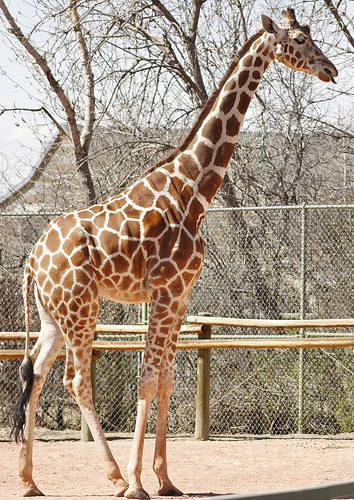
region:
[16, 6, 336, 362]
standing giraffe in enclosure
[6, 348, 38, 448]
black hair on tail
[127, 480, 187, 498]
hooves on giraffe feet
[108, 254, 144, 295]
brown spots on belly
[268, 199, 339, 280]
chain link fence and pole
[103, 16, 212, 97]
tree with no leaves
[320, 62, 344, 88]
tongue sticking out of mouth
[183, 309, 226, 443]
wood on fence post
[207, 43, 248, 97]
mane on giraffe neck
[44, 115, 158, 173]
roof of building behind trees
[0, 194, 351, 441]
fence around area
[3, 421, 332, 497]
giraffe standing on dusty ground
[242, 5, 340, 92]
giraffe sticking tongue out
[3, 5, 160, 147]
trees have no leaves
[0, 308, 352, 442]
wooden post fence in front of wired fence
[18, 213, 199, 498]
giraffe rear right leg stepping forward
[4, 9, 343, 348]
giraffe with brown pattern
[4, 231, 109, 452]
giraffe tail is brown, tan, and black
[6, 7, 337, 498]
giraffe is taller than both fences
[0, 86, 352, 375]
building in the background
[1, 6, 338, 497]
A Large Giraffe standing in the open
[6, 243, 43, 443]
The Giraffes Tail hanging low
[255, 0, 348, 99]
The Giraffe's Head held high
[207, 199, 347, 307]
Metal Chain Link Fencing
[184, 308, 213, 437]
A Wood Fence Post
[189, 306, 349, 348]
The Wooden Fence Railing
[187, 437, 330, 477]
Bare Patch of Ground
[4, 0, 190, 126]
Trees with no leaves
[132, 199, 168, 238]
The Giraffe's Spots on his back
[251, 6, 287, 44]
The Giraffe's Left Ear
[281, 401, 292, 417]
the fence is wired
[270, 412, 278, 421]
the fence is wired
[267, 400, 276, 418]
the fence is wired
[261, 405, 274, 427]
the fence is wired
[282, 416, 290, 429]
the fence is wired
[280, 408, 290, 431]
the fence is wired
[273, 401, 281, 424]
the fence is wired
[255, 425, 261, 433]
the fence is wired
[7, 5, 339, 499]
A beautiful giraffe standing inside a park.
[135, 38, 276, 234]
The long neck of a big giraffe.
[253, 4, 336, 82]
The ugly head of a large giraffe.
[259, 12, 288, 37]
The right ear of a large giraffe.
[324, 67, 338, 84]
The tongue of a wild giraffe.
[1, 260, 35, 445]
The hairy tail of a beautiful giraffe.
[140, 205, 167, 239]
One of the brown spots of a cute giraffe.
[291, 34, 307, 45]
The right eye of a large giraffe.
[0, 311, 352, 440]
The wooden fence around the park.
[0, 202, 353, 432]
A chain link fence keeping the giraffe safe.